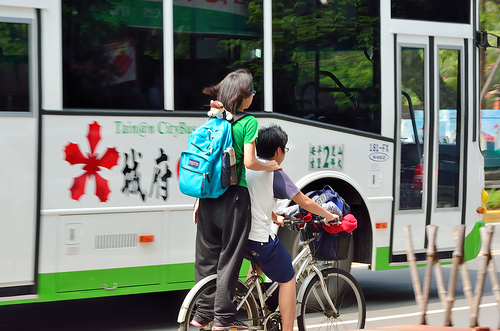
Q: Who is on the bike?
A: A boy and girl.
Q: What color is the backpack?
A: Blue.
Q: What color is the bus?
A: Green, red, white, black.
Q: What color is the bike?
A: White.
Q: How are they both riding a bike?
A: One on the seat and one on the back pegs.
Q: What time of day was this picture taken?
A: During the day.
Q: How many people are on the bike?
A: Two.